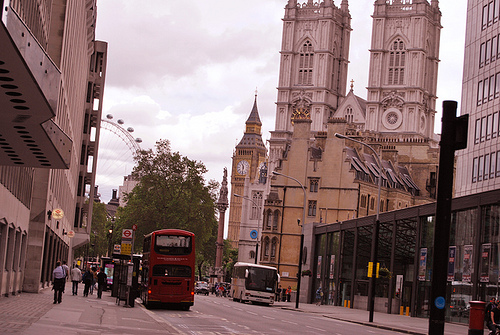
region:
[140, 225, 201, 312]
Double Decker bus in traffic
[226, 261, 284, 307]
White bus stopped at curb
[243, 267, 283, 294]
Front windshield of bus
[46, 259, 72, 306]
Pedestrian walking on sidewalk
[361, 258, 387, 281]
Yellow sign on black pole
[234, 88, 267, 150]
Steeple on tall building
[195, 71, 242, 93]
Puffy white clouds in sky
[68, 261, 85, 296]
Pedestrian walking on sidewalk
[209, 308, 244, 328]
Part of paved city street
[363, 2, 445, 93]
Ornate tower on building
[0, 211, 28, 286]
the windows of a tall building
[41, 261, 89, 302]
people walking on the street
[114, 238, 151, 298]
a black colored bus stop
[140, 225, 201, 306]
a double decker red bus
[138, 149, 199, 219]
a big fluffy big tree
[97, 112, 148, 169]
a large sized ferris wheel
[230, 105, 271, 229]
a large brown colored clock tower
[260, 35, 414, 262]
a large brown catholic church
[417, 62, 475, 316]
a long black telephone pole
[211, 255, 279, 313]
a big white tour bus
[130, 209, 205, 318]
a red double decker bus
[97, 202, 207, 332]
a bus at the bus stop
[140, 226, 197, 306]
a double decker bus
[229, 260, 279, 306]
a bus on right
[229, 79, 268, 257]
a tower on right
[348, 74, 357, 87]
a cross at the top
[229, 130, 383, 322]
a light pole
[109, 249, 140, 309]
a bus stop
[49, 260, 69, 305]
a man walking in blue shirt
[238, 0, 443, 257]
the twin towers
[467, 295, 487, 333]
a trash can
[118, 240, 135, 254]
a yellow sign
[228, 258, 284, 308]
a white bus parked alongside a road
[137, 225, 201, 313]
a red double decker bus parked alongside a road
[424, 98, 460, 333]
a black sign post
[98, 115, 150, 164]
a Ferris wheel behind a tree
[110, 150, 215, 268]
a green tree behind a bus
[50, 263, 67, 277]
a light blue shirt on a man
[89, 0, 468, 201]
a cloudy sky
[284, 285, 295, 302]
a person in a red top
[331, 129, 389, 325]
a street lamp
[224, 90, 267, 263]
the Big Ben clock tower